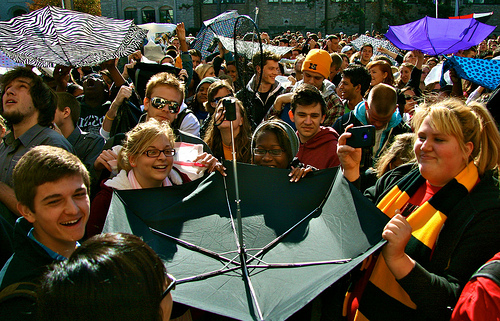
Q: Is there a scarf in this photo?
A: Yes, there is a scarf.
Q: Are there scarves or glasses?
A: Yes, there is a scarf.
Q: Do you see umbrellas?
A: Yes, there is an umbrella.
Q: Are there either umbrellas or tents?
A: Yes, there is an umbrella.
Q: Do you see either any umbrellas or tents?
A: Yes, there is an umbrella.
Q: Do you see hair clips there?
A: No, there are no hair clips.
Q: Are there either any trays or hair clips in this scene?
A: No, there are no hair clips or trays.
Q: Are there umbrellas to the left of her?
A: Yes, there is an umbrella to the left of the woman.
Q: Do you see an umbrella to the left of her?
A: Yes, there is an umbrella to the left of the woman.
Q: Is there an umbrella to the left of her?
A: Yes, there is an umbrella to the left of the woman.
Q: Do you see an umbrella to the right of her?
A: No, the umbrella is to the left of the woman.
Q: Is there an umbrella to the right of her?
A: No, the umbrella is to the left of the woman.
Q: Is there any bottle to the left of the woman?
A: No, there is an umbrella to the left of the woman.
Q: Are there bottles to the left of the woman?
A: No, there is an umbrella to the left of the woman.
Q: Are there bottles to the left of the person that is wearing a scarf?
A: No, there is an umbrella to the left of the woman.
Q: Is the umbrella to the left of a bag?
A: No, the umbrella is to the left of the woman.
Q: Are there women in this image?
A: Yes, there is a woman.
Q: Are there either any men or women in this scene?
A: Yes, there is a woman.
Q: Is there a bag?
A: No, there are no bags.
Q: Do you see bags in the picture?
A: No, there are no bags.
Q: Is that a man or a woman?
A: That is a woman.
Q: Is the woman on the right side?
A: Yes, the woman is on the right of the image.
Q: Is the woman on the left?
A: No, the woman is on the right of the image.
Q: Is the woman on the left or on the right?
A: The woman is on the right of the image.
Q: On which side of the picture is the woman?
A: The woman is on the right of the image.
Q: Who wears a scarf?
A: The woman wears a scarf.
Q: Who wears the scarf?
A: The woman wears a scarf.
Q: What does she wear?
A: The woman wears a scarf.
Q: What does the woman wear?
A: The woman wears a scarf.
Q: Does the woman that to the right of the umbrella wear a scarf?
A: Yes, the woman wears a scarf.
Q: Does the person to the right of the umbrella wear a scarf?
A: Yes, the woman wears a scarf.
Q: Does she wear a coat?
A: No, the woman wears a scarf.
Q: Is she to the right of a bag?
A: No, the woman is to the right of the umbrella.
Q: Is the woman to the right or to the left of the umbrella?
A: The woman is to the right of the umbrella.